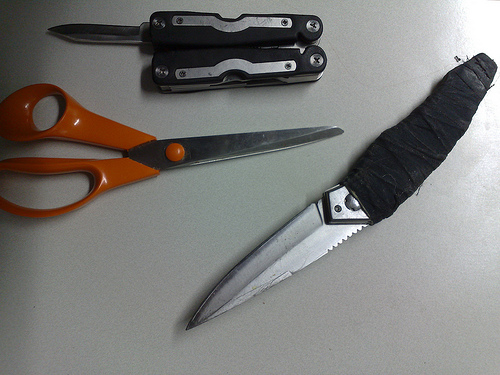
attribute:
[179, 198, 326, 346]
blade — silver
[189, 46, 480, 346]
knife — large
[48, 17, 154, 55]
blade — out, small, utility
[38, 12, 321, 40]
knife — folded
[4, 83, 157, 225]
handle — orange, plastic, shiny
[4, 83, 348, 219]
scissors — sharp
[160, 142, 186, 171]
swivel — orange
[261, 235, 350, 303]
edge — serrated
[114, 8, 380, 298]
tools — sharp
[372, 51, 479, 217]
handle — black, taped, wrapped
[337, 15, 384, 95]
table — grey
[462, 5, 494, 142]
light — reflecting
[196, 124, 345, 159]
blades — metal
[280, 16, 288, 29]
screw — small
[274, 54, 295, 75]
screw — small, silver